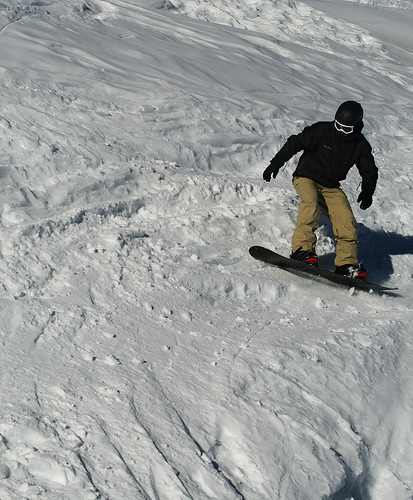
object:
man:
[261, 100, 378, 280]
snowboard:
[249, 246, 399, 294]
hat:
[336, 100, 363, 124]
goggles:
[334, 120, 354, 135]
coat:
[270, 122, 379, 196]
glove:
[262, 164, 280, 182]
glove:
[356, 191, 374, 210]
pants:
[291, 175, 360, 266]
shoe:
[291, 251, 318, 266]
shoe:
[335, 265, 368, 279]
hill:
[0, 0, 413, 500]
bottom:
[303, 256, 318, 265]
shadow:
[317, 210, 412, 284]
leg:
[291, 177, 321, 252]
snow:
[0, 0, 413, 500]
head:
[334, 101, 364, 142]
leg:
[321, 186, 359, 266]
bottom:
[357, 272, 369, 280]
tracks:
[34, 372, 247, 498]